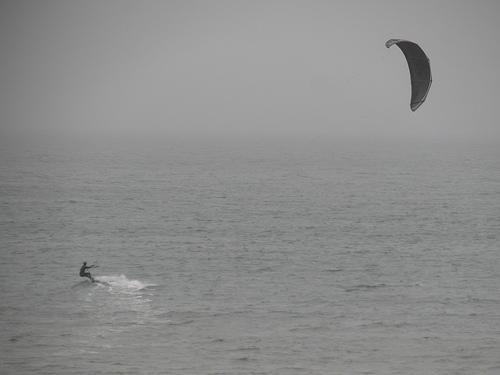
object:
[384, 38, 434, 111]
parasail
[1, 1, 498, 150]
sky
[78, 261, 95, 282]
person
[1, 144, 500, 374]
ocean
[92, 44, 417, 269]
rope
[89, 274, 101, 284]
surfboard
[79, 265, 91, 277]
wet suit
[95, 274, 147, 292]
foam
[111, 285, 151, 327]
path